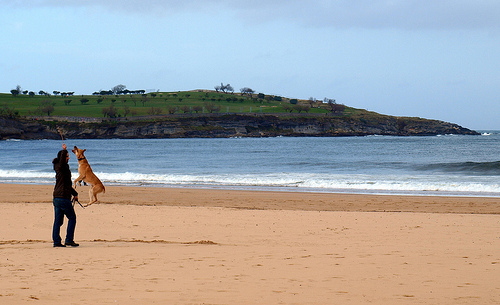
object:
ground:
[0, 177, 500, 305]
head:
[70, 145, 88, 156]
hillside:
[0, 89, 481, 140]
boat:
[479, 132, 492, 137]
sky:
[0, 2, 495, 124]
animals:
[71, 145, 106, 207]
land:
[0, 89, 483, 140]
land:
[0, 177, 497, 305]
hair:
[56, 150, 68, 160]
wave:
[1, 159, 500, 192]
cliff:
[0, 88, 482, 140]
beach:
[0, 183, 498, 305]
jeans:
[52, 197, 77, 245]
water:
[0, 129, 499, 197]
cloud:
[0, 0, 494, 132]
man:
[49, 143, 78, 247]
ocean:
[0, 131, 500, 195]